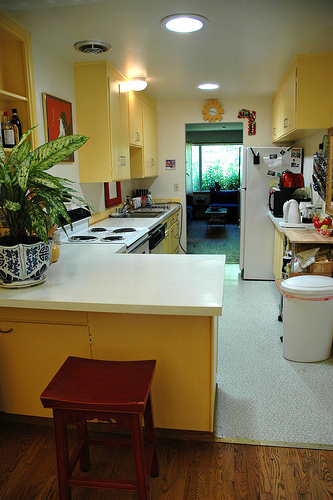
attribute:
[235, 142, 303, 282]
refrigerator — white, large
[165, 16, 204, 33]
light — on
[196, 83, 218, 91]
light — on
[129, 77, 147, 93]
light — on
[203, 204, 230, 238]
table — small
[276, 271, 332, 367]
trash can — white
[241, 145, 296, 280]
refrigirator — white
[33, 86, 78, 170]
picture — red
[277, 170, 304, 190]
coffee maker — red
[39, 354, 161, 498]
stool — wooden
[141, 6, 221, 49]
light — round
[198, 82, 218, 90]
light — ceiling, on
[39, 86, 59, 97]
frame — gold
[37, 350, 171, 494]
stool — brown, wood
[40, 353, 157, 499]
chair — wooden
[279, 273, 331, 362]
trash can — white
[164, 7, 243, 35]
light — round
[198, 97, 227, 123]
clock — orange, yellow, wall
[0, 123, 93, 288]
plant — potted, leafy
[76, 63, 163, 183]
cabinets — yellow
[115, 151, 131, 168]
handles — silver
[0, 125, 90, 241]
plant — green, blue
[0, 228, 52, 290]
pot — white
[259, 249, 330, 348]
trash can — white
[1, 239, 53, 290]
pot — white, blue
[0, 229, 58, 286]
pot — blue, white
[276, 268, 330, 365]
trashcan — small, white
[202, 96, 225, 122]
flower clock — yellow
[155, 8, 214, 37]
ceiling light — round